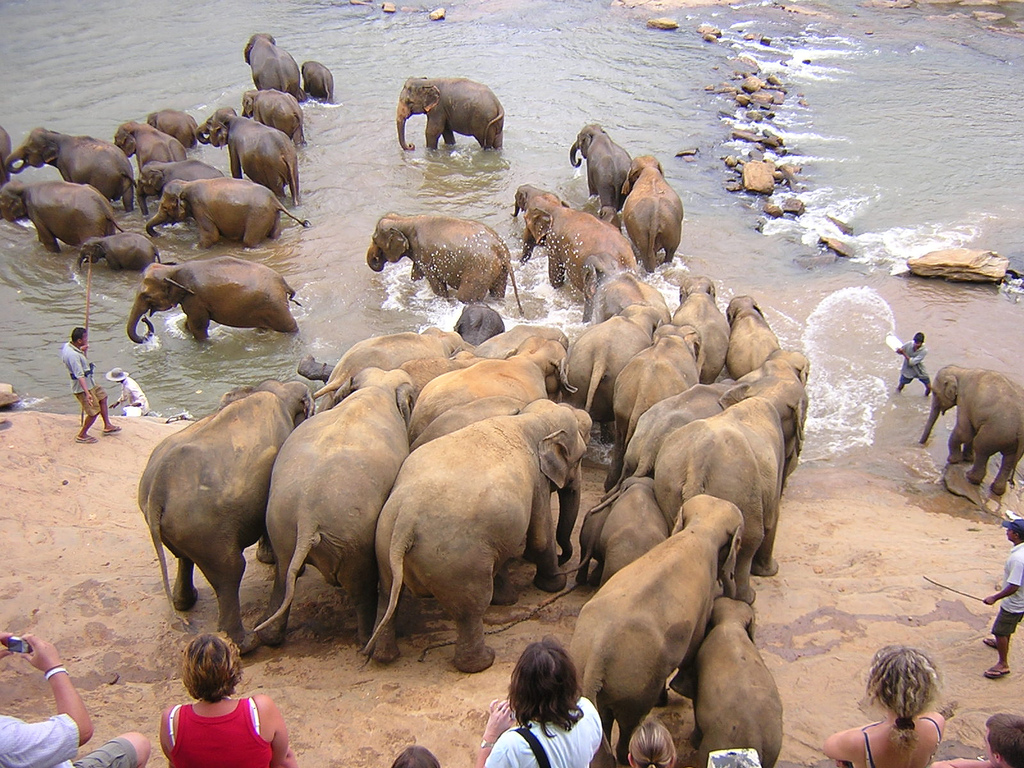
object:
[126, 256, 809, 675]
elephants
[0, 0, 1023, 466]
stream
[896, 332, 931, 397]
trainer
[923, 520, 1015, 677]
trainer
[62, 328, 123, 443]
trainer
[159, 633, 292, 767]
tourist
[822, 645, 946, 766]
tourist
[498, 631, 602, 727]
woman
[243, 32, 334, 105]
elephant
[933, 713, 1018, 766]
man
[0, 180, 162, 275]
elephant